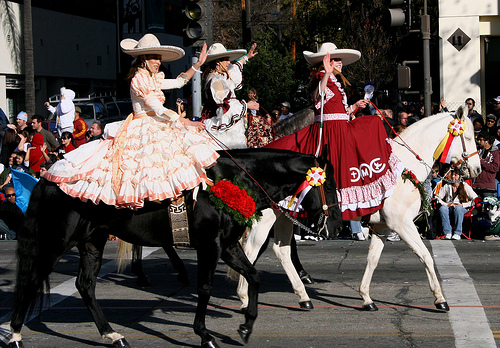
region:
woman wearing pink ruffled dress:
[65, 23, 222, 215]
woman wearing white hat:
[59, 23, 226, 215]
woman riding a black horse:
[19, 18, 333, 343]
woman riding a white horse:
[276, 28, 488, 304]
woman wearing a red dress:
[271, 18, 453, 300]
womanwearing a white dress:
[192, 35, 264, 153]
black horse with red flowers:
[41, 135, 343, 330]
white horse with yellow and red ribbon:
[319, 93, 483, 310]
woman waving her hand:
[47, 22, 227, 249]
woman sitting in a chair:
[432, 163, 475, 248]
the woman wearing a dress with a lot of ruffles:
[43, 33, 218, 210]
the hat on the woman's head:
[118, 32, 184, 62]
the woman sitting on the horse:
[42, 32, 219, 209]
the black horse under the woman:
[8, 144, 341, 346]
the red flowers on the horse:
[208, 179, 255, 218]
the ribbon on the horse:
[286, 166, 325, 214]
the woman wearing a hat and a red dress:
[258, 41, 400, 219]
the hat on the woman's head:
[302, 42, 361, 64]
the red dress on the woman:
[260, 69, 400, 221]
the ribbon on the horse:
[432, 120, 462, 163]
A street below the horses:
[0, 238, 497, 345]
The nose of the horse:
[473, 165, 482, 175]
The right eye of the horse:
[461, 130, 473, 141]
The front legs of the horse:
[360, 215, 449, 309]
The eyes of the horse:
[453, 101, 470, 118]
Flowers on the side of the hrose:
[209, 178, 255, 224]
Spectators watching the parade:
[0, 85, 497, 238]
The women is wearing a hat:
[119, 33, 183, 60]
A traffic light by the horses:
[181, 3, 210, 119]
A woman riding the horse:
[46, 33, 217, 208]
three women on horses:
[10, 33, 481, 345]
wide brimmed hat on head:
[120, 31, 184, 70]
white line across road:
[431, 237, 493, 346]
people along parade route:
[0, 100, 499, 245]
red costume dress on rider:
[260, 67, 395, 221]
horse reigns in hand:
[197, 120, 277, 200]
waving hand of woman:
[131, 42, 213, 89]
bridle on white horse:
[433, 116, 481, 178]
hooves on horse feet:
[298, 301, 453, 312]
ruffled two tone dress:
[42, 116, 215, 207]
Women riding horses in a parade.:
[6, 33, 479, 347]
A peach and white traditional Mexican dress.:
[41, 68, 219, 208]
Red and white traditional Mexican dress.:
[261, 70, 403, 220]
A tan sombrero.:
[117, 33, 185, 62]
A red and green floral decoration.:
[203, 173, 259, 223]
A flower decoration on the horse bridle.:
[304, 165, 326, 187]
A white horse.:
[236, 102, 481, 312]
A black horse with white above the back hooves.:
[8, 140, 341, 345]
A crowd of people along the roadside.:
[0, 83, 498, 239]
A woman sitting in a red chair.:
[432, 169, 479, 242]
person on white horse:
[269, 25, 490, 240]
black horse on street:
[11, 134, 343, 336]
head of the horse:
[256, 140, 359, 247]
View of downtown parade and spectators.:
[0, 4, 497, 346]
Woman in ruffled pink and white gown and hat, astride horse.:
[62, 31, 198, 189]